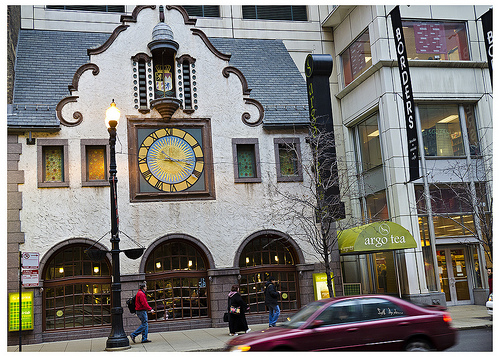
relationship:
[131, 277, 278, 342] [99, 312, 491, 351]
people on street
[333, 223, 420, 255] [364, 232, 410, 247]
awning has name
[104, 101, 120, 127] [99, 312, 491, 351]
light on street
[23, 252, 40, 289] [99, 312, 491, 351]
sign on street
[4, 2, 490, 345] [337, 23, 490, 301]
building has windows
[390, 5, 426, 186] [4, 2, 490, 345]
sign on building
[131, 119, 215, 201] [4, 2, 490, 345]
clock on building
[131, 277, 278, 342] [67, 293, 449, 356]
person on sidewalk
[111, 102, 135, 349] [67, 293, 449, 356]
pole on sidewalk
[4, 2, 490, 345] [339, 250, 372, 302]
building has entrance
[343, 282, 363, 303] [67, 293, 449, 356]
brick on sidewalk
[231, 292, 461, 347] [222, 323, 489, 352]
car on road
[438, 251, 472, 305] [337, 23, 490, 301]
double doors to building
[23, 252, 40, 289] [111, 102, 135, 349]
sign on pole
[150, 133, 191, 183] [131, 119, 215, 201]
yellow sun in clock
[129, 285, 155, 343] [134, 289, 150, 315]
man has red shirt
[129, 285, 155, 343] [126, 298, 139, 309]
man has black backpack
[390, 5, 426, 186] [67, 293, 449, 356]
banner on sidewalk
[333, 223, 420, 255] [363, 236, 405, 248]
awning says argo tea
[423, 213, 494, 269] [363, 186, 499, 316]
light in store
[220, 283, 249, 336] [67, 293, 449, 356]
person standing on sidewalk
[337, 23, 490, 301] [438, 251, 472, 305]
building has double doors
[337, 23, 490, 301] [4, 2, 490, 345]
window on building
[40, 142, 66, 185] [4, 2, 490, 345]
window on building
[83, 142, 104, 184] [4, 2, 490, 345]
window on building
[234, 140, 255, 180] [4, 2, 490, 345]
window on building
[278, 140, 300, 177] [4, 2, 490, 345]
window on building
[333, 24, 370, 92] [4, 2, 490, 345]
window on building